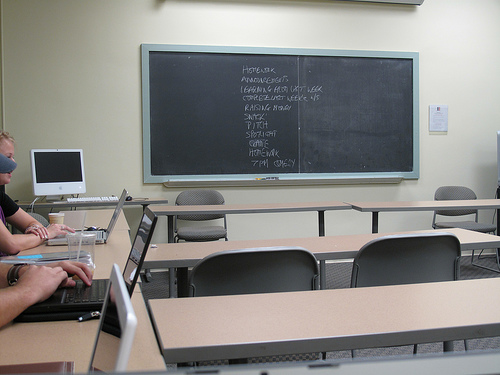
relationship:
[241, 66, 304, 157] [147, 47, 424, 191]
writing on chalkboard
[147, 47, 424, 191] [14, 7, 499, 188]
chalkboard attached to wall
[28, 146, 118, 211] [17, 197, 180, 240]
computer sitting on desk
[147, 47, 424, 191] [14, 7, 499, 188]
chalkboard on wall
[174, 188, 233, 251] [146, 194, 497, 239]
chair under table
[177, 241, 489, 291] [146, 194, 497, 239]
chairs by table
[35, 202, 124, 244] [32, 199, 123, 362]
laptop on top of desk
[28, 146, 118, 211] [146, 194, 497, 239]
computer on table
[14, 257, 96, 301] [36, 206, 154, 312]
hands on top of computer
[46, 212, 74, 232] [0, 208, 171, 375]
cup sitting on desk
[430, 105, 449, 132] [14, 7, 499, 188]
paper on wall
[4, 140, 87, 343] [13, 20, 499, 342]
people in classroom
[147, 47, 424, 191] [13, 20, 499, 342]
chalkboard in classroom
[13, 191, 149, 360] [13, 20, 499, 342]
laptops in classroom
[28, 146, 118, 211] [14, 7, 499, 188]
computer next to wall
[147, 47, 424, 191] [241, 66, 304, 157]
chalkboard has writing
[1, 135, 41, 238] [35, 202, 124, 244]
person on laptop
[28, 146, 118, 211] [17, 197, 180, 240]
computer on desk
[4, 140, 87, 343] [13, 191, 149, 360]
people using laptops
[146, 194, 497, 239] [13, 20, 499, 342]
table in classroom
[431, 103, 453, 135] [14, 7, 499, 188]
paper on wall